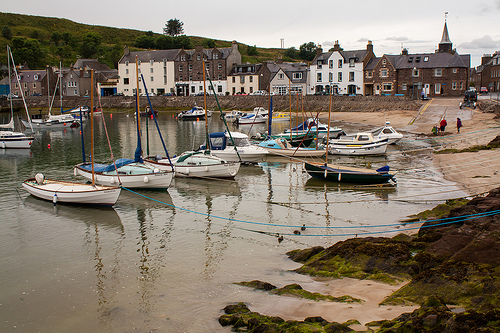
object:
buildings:
[364, 47, 472, 96]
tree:
[11, 36, 46, 68]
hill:
[0, 10, 187, 42]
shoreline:
[253, 96, 499, 194]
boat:
[297, 156, 400, 188]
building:
[308, 39, 379, 95]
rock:
[284, 245, 325, 262]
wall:
[118, 61, 171, 97]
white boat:
[21, 173, 122, 207]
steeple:
[438, 11, 452, 44]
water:
[0, 104, 491, 328]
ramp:
[409, 94, 469, 139]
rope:
[119, 183, 499, 231]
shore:
[217, 191, 499, 331]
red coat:
[440, 119, 448, 127]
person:
[437, 117, 448, 137]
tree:
[162, 18, 185, 37]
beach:
[394, 141, 499, 332]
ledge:
[280, 39, 284, 49]